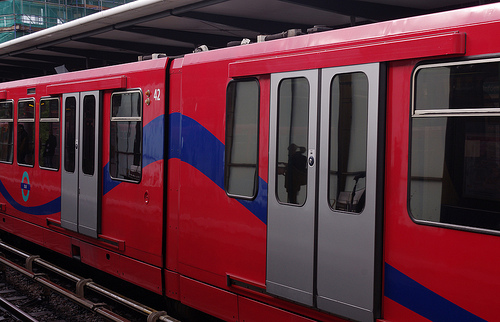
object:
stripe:
[0, 111, 486, 322]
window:
[327, 72, 369, 215]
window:
[276, 76, 309, 207]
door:
[59, 90, 100, 240]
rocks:
[11, 262, 117, 322]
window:
[108, 91, 143, 182]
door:
[265, 62, 389, 322]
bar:
[228, 24, 466, 77]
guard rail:
[0, 0, 130, 40]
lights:
[144, 90, 150, 106]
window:
[224, 76, 260, 198]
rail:
[0, 0, 500, 322]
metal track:
[1, 298, 39, 322]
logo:
[21, 171, 30, 202]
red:
[188, 59, 224, 101]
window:
[409, 62, 500, 233]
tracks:
[0, 232, 216, 322]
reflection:
[277, 142, 307, 204]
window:
[407, 52, 499, 236]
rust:
[0, 287, 19, 319]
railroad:
[0, 229, 220, 322]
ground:
[0, 270, 103, 322]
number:
[154, 88, 161, 100]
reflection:
[330, 73, 368, 213]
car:
[0, 0, 500, 322]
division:
[160, 59, 170, 296]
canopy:
[0, 0, 496, 62]